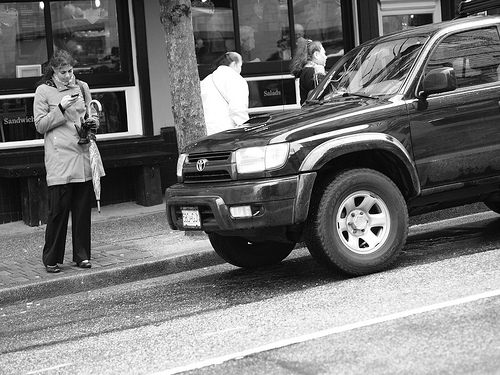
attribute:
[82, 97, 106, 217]
umbrella — closed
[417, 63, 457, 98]
mirror — side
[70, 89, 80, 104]
smartphone — black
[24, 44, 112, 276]
woman — standing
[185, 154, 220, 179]
logo — Toyota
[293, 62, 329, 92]
coat — black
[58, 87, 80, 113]
hand — woman's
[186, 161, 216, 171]
logo — Brand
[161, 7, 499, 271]
car — parked 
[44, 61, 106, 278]
woman — holding